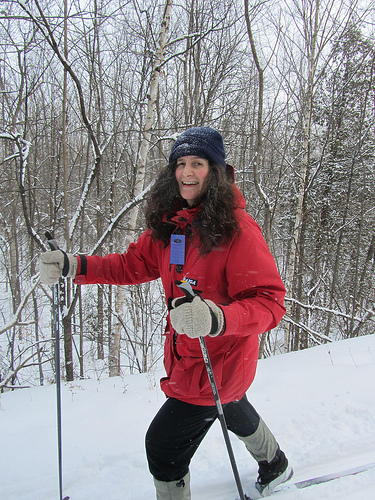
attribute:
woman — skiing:
[63, 115, 294, 492]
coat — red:
[71, 183, 286, 396]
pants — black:
[144, 396, 284, 494]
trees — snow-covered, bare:
[1, 6, 371, 335]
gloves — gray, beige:
[34, 243, 225, 336]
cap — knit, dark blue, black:
[171, 124, 230, 165]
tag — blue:
[173, 234, 185, 263]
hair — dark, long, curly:
[146, 163, 237, 245]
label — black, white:
[184, 276, 198, 290]